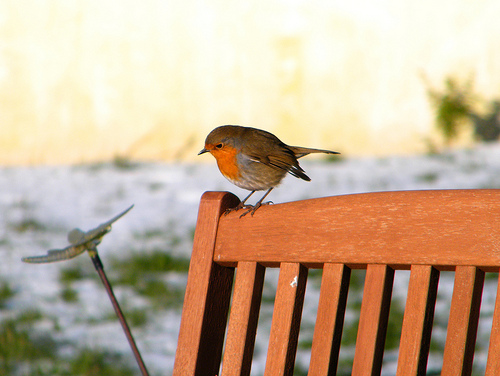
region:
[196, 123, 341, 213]
an orange and brown bird on a bench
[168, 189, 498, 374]
a brown wooden bench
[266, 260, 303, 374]
a wooden rail on a bench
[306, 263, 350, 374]
a wooden rail on a bench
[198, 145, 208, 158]
a black birds beak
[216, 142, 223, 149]
a black birds eye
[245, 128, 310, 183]
a brown birds wing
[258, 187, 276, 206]
a thin birds leg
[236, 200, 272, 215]
a birds foot on a bench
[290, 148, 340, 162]
a brown bird tail feather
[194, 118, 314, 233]
A bird on top of a bench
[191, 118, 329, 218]
A bird standing on a bench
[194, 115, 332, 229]
A bird perched on a bench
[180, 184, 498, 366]
A wooden bench with a bird on i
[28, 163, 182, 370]
snow on the ground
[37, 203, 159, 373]
A solar light near a bench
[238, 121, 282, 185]
Feathers on a bird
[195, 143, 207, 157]
The beak on a bird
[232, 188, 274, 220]
Bird feet on a bench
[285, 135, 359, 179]
The tail of a bird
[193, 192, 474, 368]
bench made of wood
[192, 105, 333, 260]
a small bird perched on the bench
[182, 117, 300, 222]
a small bird perched on the bench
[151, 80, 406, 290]
a bird on a bench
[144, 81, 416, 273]
a small bird on a bench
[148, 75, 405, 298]
a bird on a wooden bench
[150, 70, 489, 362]
a small bird on a wooden bench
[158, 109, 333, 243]
a bird on a small bench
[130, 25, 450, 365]
a bird on an outside bench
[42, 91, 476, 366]
a small bird on an outside bench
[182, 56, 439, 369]
a small bird standing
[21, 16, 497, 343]
Picture taken outdoors.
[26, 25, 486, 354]
Picture taken during the day.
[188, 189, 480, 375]
A bird is on the back of a chair.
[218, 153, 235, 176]
The bird has a orange chest.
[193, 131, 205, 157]
The bird has a short beak.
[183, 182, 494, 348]
The chair is made of wood.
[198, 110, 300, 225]
The bird is standing.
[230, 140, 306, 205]
The bird is looking away.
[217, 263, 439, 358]
The chair has slats.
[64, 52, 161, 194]
The background is blurry.